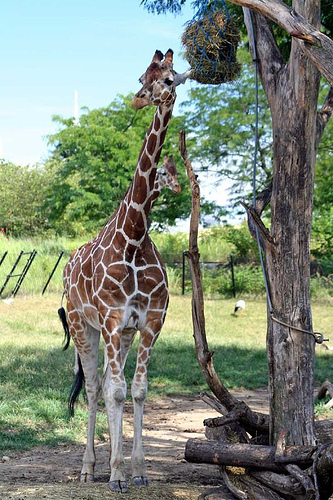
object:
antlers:
[153, 48, 174, 63]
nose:
[133, 93, 139, 103]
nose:
[173, 182, 180, 191]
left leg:
[131, 334, 152, 458]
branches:
[179, 129, 219, 381]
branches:
[239, 200, 272, 248]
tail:
[57, 287, 70, 353]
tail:
[65, 351, 85, 423]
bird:
[234, 300, 246, 315]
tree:
[238, 0, 331, 444]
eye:
[164, 78, 173, 86]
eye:
[162, 172, 167, 175]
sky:
[0, 0, 156, 72]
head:
[132, 50, 195, 111]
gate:
[182, 259, 234, 299]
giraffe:
[59, 49, 192, 495]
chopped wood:
[183, 394, 333, 498]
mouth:
[131, 100, 142, 110]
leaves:
[206, 0, 246, 50]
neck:
[119, 116, 171, 242]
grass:
[2, 294, 60, 432]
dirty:
[3, 443, 80, 497]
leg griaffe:
[72, 325, 100, 464]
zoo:
[0, 0, 333, 500]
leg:
[104, 324, 127, 466]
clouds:
[16, 125, 44, 164]